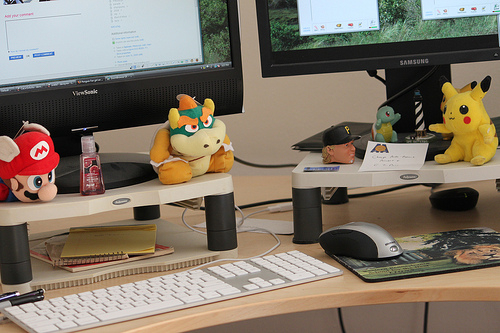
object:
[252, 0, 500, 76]
monitor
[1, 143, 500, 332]
desk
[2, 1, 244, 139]
monitor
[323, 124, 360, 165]
head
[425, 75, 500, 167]
animal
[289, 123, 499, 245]
stand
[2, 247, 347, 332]
keyboard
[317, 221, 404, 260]
mouse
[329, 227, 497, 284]
pad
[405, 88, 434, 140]
statue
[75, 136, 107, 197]
bottle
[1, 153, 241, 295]
stand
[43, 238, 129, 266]
pads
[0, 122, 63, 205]
toy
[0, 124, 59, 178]
hat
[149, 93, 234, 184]
figure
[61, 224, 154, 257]
notepad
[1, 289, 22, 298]
pens